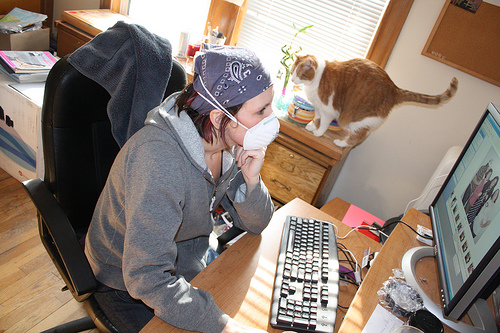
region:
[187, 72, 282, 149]
A white mask.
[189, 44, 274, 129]
A grey bandana.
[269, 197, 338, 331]
A black keyboard.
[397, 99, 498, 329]
A silver and black flatscreen monitor.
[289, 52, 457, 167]
An orange and white cat.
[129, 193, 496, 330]
A brown wooden computer desk.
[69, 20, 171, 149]
A dark grey towel.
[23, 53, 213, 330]
A black desk chair.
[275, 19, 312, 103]
A green houseplant.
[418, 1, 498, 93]
A brown bulletin board.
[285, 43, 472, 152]
a cat on a side table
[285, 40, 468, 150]
cat color is brown and white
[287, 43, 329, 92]
head and neck of cat is color white and brown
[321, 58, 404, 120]
body of cat is brown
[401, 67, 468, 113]
tail of cat is brown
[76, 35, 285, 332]
woman wears a mask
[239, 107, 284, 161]
a mask color white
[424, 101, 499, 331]
screen of a computer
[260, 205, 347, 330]
keyboard of computer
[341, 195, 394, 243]
pink paper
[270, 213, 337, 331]
a wired computer keyboard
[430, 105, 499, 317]
a computer display monitor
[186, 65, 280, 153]
a white face mask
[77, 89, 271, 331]
a grey sweatshirt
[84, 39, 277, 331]
a woman sitting at a desk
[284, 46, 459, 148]
a brown and white cat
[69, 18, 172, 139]
a dark blue towel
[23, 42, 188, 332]
a black swivel chair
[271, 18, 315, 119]
a small green plant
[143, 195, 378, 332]
a brown keyboard tray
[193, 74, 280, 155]
white face mask with straps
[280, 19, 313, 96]
green lucky bamboo plant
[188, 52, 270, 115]
gray handkerchief on woman's head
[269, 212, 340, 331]
grey computer keyboard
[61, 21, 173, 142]
fluffy gray towel on the back of the chair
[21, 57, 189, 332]
black computer chair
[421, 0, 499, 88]
empty bulletin board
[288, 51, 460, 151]
tabby cat with white spots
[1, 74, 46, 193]
white cardboard box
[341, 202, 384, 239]
pink notepad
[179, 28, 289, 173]
Head of a person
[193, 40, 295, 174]
Head of a woman person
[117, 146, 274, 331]
Hand of a person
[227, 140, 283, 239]
Hand of a person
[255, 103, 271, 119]
Eye of a person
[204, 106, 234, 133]
Ear of a person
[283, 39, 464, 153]
This is a cat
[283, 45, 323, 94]
Head of a cat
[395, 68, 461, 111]
Tail of a cat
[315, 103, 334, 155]
Leg of a cat